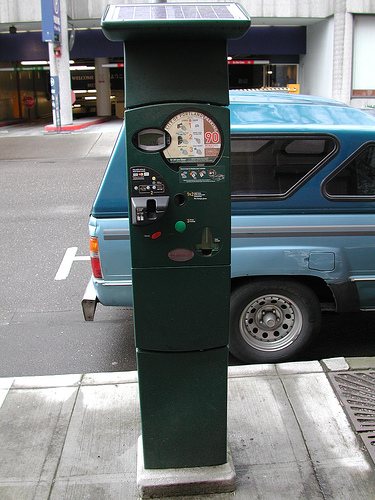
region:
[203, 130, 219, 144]
number 90 on a meter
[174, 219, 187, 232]
green button on a meter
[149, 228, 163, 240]
red button on a meter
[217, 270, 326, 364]
back tire of a van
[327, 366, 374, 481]
metal plate on the sidewalk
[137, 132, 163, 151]
display on the meter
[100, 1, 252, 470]
the parking meter is large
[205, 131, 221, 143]
the number 90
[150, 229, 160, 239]
the red button is small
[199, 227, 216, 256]
the slot for coins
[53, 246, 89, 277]
the white line in the road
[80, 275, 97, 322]
the bumper is metal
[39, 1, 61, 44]
the blue sign across the street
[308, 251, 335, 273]
the gas cover on the side of the truck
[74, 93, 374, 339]
light blue truck with dark blue camper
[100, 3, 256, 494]
green post on the sidewalk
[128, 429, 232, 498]
cement base of green post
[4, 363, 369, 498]
sidewalk next to truck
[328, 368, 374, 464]
grate in the sidewalk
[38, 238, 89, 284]
white lines painted on the street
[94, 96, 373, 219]
camper on the truck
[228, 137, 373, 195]
windows in the camper shell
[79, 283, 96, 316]
bumper on the truck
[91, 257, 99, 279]
brake light on the truck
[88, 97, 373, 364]
side of parked truck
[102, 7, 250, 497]
parking meter on cement base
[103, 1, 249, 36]
solar panel of parking meter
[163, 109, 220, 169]
instructions on parking meter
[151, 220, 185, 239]
green and red buttons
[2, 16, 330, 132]
opening of parking garage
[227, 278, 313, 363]
tire on side of truck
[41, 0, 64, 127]
blue sign on pole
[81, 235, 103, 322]
two lights over bumper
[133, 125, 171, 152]
digital display of parking meter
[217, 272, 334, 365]
Tire on a truck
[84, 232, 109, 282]
Tail light on a truck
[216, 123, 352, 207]
Window on a truck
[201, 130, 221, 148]
90 written on a post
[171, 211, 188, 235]
Green button on a post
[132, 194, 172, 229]
Credit card slot on a post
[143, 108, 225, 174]
Instructions on a parking meter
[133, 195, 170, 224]
Credit card slot on a parking meter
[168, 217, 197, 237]
Green button on a parking meter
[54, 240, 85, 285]
a white line painted on pavement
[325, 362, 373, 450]
a drain gate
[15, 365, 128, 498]
a concrete sidewalk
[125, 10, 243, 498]
a parking meter mounted to a sidewalk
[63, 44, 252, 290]
A green parking meter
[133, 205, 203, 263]
A green and red button on a parking meter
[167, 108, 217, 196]
A sticker telling you how to use the parking meter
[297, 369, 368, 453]
A metal drain on the sidewalk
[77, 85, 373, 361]
a car on a street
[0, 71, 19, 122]
a window on a building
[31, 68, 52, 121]
a window on a building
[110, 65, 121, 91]
a window on a building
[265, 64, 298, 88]
a window on a building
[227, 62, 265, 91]
a window on a building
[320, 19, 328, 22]
a brick in a wall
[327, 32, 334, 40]
a brick in a wall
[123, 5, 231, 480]
tall green parking meter